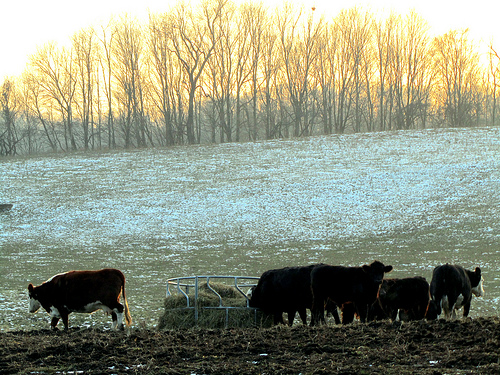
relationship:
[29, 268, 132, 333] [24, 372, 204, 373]
cow walking on beach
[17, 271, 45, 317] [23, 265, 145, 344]
head of cow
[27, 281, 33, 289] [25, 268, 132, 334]
ear of cow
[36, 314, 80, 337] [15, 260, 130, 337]
legs of cow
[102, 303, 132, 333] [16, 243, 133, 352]
legs of cow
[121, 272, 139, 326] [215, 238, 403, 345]
tail of cow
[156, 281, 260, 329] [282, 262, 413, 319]
hay of cows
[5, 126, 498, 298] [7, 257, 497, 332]
hill behind cows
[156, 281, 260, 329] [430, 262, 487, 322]
hay near cow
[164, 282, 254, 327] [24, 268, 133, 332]
hay near cow